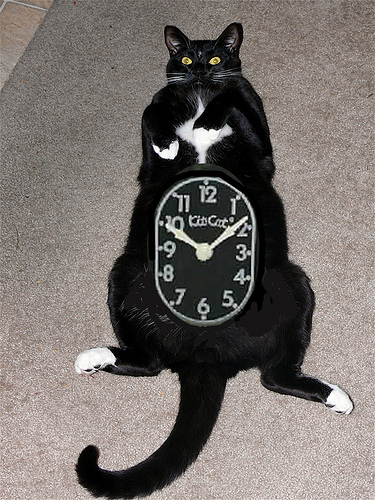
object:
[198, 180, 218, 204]
number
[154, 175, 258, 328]
clock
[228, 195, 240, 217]
number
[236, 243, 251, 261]
number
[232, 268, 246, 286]
number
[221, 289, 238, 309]
number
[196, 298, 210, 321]
number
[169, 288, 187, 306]
number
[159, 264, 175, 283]
number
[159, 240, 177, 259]
number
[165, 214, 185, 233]
number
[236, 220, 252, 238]
number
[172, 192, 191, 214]
number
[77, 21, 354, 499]
cat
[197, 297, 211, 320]
6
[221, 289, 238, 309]
5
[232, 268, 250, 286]
4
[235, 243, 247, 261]
3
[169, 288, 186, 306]
7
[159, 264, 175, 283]
8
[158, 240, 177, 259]
9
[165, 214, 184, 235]
10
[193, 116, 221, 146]
paw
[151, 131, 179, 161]
paw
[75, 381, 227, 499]
tail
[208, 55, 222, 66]
eye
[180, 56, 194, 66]
eye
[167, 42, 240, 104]
face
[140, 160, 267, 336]
stomach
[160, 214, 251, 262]
time